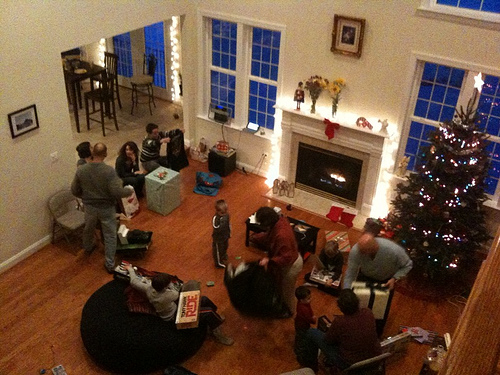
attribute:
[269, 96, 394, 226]
fireplace — decorated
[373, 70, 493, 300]
tree — Christmas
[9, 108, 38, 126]
picture — Small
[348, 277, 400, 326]
present — wrapped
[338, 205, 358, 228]
christmas stocking — red, white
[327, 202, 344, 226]
christmas stocking — red, white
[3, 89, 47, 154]
picture — framed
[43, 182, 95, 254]
chair — beige 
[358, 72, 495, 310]
christmas tree — decorated, lit up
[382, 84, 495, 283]
tree — decorated, Christmas, lit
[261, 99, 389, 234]
fireplace — white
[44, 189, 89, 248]
chair — gray, folding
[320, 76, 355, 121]
flowers — yellow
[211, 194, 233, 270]
boy — young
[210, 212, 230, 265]
pajamas — gray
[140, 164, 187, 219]
box — large, wrapped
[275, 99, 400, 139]
mantle — white